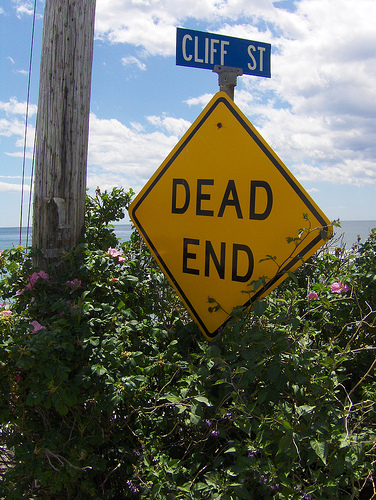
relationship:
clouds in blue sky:
[0, 0, 376, 196] [1, 5, 373, 222]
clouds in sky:
[0, 0, 376, 196] [2, 1, 364, 216]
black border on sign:
[231, 102, 275, 164] [118, 90, 338, 347]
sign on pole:
[118, 90, 338, 347] [31, 0, 94, 270]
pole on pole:
[17, 2, 39, 247] [34, 1, 92, 243]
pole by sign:
[212, 62, 241, 104] [127, 94, 331, 328]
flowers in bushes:
[331, 281, 352, 293] [9, 244, 371, 488]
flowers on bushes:
[293, 483, 310, 499] [1, 185, 374, 498]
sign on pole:
[127, 90, 333, 343] [212, 62, 243, 103]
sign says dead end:
[127, 90, 333, 343] [147, 164, 283, 289]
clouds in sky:
[0, 0, 376, 196] [111, 15, 346, 163]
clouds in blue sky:
[284, 8, 374, 164] [0, 1, 375, 226]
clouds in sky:
[0, 0, 376, 196] [90, 24, 180, 155]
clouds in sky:
[0, 0, 376, 196] [96, 0, 374, 226]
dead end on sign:
[168, 175, 273, 284] [118, 90, 338, 347]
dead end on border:
[168, 175, 273, 284] [131, 96, 329, 338]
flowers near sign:
[301, 277, 349, 301] [127, 90, 333, 343]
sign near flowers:
[127, 90, 333, 343] [301, 277, 349, 301]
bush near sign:
[132, 303, 322, 463] [127, 90, 333, 343]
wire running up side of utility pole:
[11, 164, 35, 184] [31, 129, 90, 245]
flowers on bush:
[27, 318, 44, 332] [1, 187, 374, 498]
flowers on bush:
[105, 246, 120, 256] [1, 187, 374, 498]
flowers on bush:
[307, 292, 319, 301] [1, 187, 374, 498]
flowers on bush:
[328, 280, 348, 293] [1, 187, 374, 498]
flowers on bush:
[37, 270, 48, 280] [1, 187, 374, 498]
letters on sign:
[169, 175, 275, 220] [118, 90, 338, 347]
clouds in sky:
[0, 0, 376, 196] [99, 36, 190, 161]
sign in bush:
[118, 90, 338, 347] [24, 261, 243, 441]